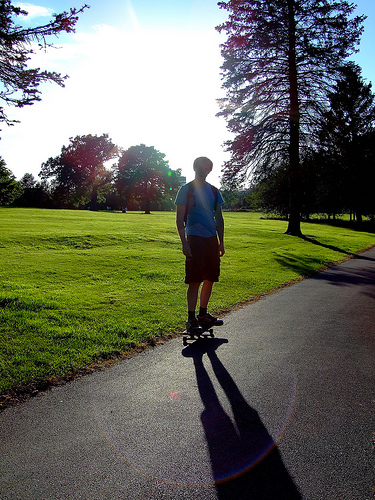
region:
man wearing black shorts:
[179, 237, 222, 286]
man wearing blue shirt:
[173, 176, 224, 239]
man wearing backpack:
[179, 181, 221, 223]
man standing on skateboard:
[179, 314, 227, 347]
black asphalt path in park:
[2, 248, 373, 493]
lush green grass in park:
[6, 202, 364, 402]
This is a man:
[172, 147, 242, 375]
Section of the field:
[22, 289, 132, 365]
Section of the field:
[78, 242, 145, 297]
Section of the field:
[215, 205, 274, 247]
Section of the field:
[260, 231, 318, 289]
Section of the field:
[6, 197, 121, 241]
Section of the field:
[223, 195, 288, 259]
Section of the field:
[22, 198, 180, 315]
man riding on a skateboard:
[174, 324, 213, 347]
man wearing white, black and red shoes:
[185, 312, 223, 331]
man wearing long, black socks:
[187, 306, 207, 319]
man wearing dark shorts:
[184, 234, 219, 283]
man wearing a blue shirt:
[174, 180, 225, 238]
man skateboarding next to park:
[0, 0, 373, 411]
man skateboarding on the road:
[1, 245, 374, 498]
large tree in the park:
[213, 0, 367, 236]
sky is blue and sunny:
[0, 0, 373, 190]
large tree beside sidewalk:
[214, 0, 367, 236]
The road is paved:
[7, 269, 373, 497]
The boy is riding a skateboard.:
[171, 316, 219, 347]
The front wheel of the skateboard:
[171, 334, 201, 351]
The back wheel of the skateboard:
[197, 326, 221, 337]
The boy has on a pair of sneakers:
[181, 312, 230, 338]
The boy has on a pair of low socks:
[177, 299, 212, 319]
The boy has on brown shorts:
[178, 234, 224, 285]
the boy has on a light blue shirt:
[170, 180, 233, 251]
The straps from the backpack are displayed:
[175, 182, 222, 220]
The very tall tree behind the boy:
[209, 3, 371, 239]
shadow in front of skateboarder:
[165, 152, 303, 492]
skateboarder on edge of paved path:
[172, 148, 228, 351]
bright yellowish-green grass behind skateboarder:
[5, 199, 371, 389]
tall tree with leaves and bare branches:
[212, 3, 365, 236]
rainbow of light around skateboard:
[78, 301, 305, 485]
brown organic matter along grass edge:
[7, 241, 370, 407]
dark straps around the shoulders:
[173, 178, 222, 220]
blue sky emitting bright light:
[3, 5, 373, 191]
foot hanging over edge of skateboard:
[176, 305, 227, 346]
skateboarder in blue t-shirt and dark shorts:
[174, 181, 225, 289]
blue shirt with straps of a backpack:
[174, 177, 225, 241]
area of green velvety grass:
[0, 206, 308, 338]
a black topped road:
[1, 249, 373, 499]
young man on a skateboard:
[173, 154, 226, 349]